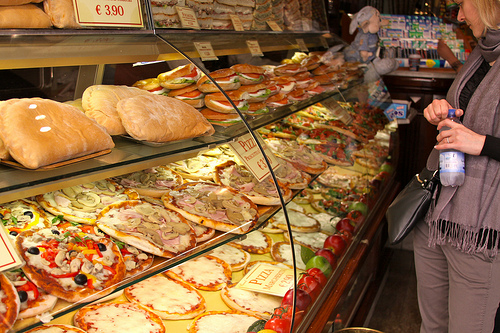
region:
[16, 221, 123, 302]
pizza in a display shelf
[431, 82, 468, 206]
water bottle in woman's hand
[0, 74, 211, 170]
calzones on a shelf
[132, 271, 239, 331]
cheese pizza on display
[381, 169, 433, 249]
purse of a woman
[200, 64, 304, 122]
sandwiches on display shelf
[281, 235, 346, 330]
apples lined up in dispaly shelf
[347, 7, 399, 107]
woman shopping in a store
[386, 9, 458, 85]
items on display in a store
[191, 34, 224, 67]
sale sign on glass display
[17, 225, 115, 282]
pizza in a case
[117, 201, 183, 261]
pizza in a case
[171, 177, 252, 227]
pizza in a case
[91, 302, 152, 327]
pizza in a case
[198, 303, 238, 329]
pizza in a case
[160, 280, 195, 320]
pizza in a case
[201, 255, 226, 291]
pizza in a case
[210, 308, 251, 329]
pizza in a case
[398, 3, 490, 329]
woman holding bottle of water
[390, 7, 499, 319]
woman wearing gray scarf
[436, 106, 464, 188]
Water bottle in woman's hands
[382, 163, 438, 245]
Black purse carried by woman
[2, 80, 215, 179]
Unbaked calzones for sale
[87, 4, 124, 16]
Price of product in Euros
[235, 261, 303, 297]
Price for unbaked pizzas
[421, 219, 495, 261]
Fringes on woman's scarf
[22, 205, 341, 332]
Unbaked cheese pizzas for sale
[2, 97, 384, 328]
Unbaked pizzas with different toppings for sale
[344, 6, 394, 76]
Stuffed doll on display case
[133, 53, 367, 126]
Sandwiches for sale in display case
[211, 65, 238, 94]
Large sandwich on display.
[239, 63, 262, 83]
Large sandwich on display.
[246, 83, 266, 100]
Large sandwich on display.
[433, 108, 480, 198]
Woman holding water bottle.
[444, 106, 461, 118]
Blue cap on water bottle.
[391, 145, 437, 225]
Woman wearing black purse.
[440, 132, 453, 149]
Band around woman's finger.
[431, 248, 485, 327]
Woman wearing gray pants.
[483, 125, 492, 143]
Woman wearing black shirt.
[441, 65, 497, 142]
Gray scarf around woman's neck.